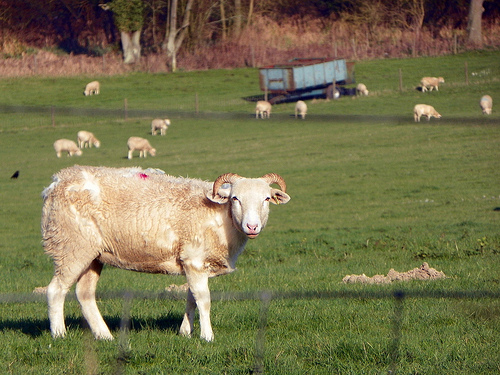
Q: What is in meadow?
A: Sheep.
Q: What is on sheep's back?
A: Red dot.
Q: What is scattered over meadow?
A: Sheep.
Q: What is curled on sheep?
A: Horns.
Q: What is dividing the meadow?
A: A fence.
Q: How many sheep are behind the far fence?
A: 1.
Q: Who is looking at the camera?
A: A sheep.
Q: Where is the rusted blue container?
A: The far field.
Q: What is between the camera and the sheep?
A: A fence.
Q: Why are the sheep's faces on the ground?
A: To eat grass.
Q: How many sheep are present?
A: 12.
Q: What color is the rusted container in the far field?
A: Blue.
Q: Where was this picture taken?
A: A farm.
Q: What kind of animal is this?
A: Sheep.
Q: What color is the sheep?
A: Brown.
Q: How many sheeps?
A: 12.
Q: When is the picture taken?
A: Daytime.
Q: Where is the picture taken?
A: At a farm.